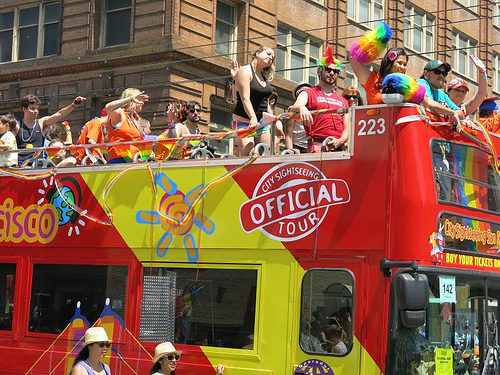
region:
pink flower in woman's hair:
[386, 49, 398, 60]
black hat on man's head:
[423, 57, 450, 76]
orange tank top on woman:
[104, 112, 144, 162]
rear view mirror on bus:
[378, 259, 430, 329]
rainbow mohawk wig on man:
[316, 45, 343, 69]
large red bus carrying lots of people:
[2, 104, 499, 374]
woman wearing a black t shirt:
[233, 68, 277, 113]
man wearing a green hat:
[424, 55, 455, 78]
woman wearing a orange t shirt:
[109, 110, 142, 146]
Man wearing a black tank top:
[12, 119, 50, 154]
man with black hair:
[20, 92, 43, 114]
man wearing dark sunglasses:
[184, 107, 204, 116]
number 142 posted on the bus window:
[438, 269, 460, 312]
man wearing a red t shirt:
[295, 80, 351, 139]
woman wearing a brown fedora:
[78, 314, 118, 353]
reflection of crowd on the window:
[308, 290, 350, 353]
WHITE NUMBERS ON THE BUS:
[356, 117, 391, 134]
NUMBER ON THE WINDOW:
[438, 277, 462, 298]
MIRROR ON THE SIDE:
[388, 260, 433, 328]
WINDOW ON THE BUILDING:
[94, 6, 126, 47]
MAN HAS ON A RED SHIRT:
[318, 118, 343, 130]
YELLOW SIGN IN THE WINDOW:
[433, 345, 457, 371]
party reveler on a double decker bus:
[0, 89, 85, 160]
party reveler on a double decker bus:
[105, 87, 147, 157]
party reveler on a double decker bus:
[227, 41, 274, 153]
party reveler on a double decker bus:
[290, 48, 345, 151]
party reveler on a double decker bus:
[348, 23, 415, 100]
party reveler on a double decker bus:
[410, 46, 468, 126]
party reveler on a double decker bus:
[445, 54, 489, 116]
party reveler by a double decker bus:
[64, 323, 122, 374]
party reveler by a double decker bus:
[147, 340, 181, 373]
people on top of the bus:
[7, 60, 489, 195]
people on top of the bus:
[17, 42, 433, 219]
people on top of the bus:
[18, 43, 472, 197]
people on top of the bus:
[0, 33, 416, 216]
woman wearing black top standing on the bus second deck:
[232, 44, 274, 156]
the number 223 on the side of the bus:
[355, 115, 387, 137]